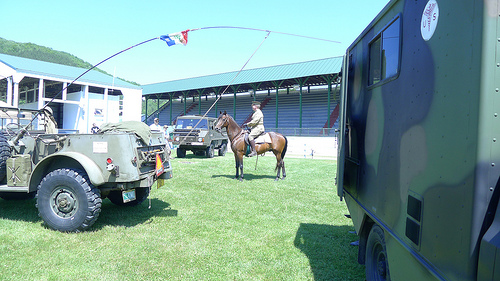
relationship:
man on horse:
[245, 99, 264, 157] [215, 111, 286, 181]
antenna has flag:
[11, 26, 341, 153] [160, 29, 190, 45]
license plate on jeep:
[122, 189, 137, 202] [1, 106, 172, 231]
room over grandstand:
[138, 56, 342, 95] [146, 89, 349, 136]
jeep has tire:
[1, 106, 172, 231] [35, 169, 102, 232]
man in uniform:
[245, 99, 264, 157] [248, 109, 264, 140]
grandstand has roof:
[146, 89, 349, 136] [143, 54, 344, 93]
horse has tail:
[215, 111, 286, 181] [281, 134, 287, 163]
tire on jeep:
[35, 169, 102, 232] [1, 106, 172, 231]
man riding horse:
[245, 99, 264, 157] [215, 111, 286, 181]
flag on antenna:
[160, 29, 190, 45] [11, 26, 341, 153]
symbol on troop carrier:
[421, 1, 440, 42] [337, 1, 500, 279]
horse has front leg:
[215, 111, 286, 181] [236, 152, 244, 181]